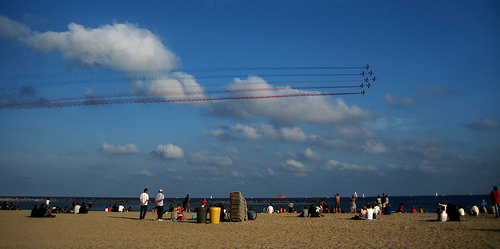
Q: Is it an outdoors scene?
A: Yes, it is outdoors.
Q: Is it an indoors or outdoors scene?
A: It is outdoors.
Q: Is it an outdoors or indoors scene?
A: It is outdoors.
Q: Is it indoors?
A: No, it is outdoors.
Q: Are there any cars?
A: No, there are no cars.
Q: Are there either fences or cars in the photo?
A: No, there are no cars or fences.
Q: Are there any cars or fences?
A: No, there are no cars or fences.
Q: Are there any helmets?
A: No, there are no helmets.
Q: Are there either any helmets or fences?
A: No, there are no helmets or fences.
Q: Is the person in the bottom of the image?
A: Yes, the person is in the bottom of the image.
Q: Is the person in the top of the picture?
A: No, the person is in the bottom of the image.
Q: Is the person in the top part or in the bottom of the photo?
A: The person is in the bottom of the image.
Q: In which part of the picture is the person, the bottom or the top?
A: The person is in the bottom of the image.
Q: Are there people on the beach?
A: Yes, there is a person on the beach.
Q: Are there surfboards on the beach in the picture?
A: No, there is a person on the beach.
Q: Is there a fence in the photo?
A: No, there are no fences.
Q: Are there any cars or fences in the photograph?
A: No, there are no fences or cars.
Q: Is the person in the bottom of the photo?
A: Yes, the person is in the bottom of the image.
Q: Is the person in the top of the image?
A: No, the person is in the bottom of the image.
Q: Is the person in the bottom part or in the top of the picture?
A: The person is in the bottom of the image.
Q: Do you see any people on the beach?
A: Yes, there is a person on the beach.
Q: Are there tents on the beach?
A: No, there is a person on the beach.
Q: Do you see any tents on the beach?
A: No, there is a person on the beach.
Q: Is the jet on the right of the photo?
A: Yes, the jet is on the right of the image.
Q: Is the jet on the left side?
A: No, the jet is on the right of the image.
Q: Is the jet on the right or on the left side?
A: The jet is on the right of the image.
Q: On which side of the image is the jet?
A: The jet is on the right of the image.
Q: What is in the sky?
A: The jet is in the sky.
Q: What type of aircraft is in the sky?
A: The aircraft is a jet.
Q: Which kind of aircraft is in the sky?
A: The aircraft is a jet.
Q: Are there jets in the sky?
A: Yes, there is a jet in the sky.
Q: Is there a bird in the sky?
A: No, there is a jet in the sky.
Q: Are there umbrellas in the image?
A: No, there are no umbrellas.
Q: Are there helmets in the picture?
A: No, there are no helmets.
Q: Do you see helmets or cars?
A: No, there are no helmets or cars.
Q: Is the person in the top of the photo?
A: No, the person is in the bottom of the image.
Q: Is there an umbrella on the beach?
A: No, there is a person on the beach.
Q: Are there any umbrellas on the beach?
A: No, there is a person on the beach.